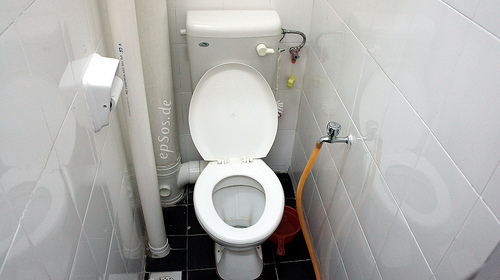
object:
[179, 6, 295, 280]
toilet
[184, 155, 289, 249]
seat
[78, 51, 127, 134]
holder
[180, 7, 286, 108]
tank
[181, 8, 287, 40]
cover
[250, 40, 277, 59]
handle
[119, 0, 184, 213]
pipe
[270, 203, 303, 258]
pan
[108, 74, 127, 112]
tissue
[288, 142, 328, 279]
hose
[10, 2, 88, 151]
tile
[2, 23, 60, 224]
tile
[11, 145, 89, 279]
tile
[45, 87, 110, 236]
tile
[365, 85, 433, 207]
tile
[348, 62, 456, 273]
reflection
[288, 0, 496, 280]
wall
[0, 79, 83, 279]
reflection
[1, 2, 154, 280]
wall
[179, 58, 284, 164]
lid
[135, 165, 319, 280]
floor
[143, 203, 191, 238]
tile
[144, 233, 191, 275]
tile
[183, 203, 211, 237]
tile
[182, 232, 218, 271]
tile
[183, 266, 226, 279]
tile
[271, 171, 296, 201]
tile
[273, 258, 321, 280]
tile